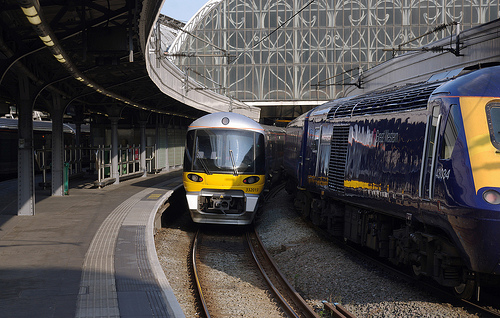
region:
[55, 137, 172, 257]
The station has no people.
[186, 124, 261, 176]
The train has one big window.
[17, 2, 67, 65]
The lights at the station are turned on.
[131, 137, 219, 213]
The train is next to the platform.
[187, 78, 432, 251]
The train is next to the big, blue train.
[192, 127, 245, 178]
The train has two windshield wipers.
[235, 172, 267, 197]
The train has numbers on it.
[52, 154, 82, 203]
The trash can is next to the pole.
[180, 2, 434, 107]
The walkway is above the trains.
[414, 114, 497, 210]
The train is blue and yellow.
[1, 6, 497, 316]
two trains on railroad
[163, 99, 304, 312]
train is on railroad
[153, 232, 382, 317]
railroad is covered with gravel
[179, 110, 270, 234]
front train is yellow and gray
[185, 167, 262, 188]
the headlights of train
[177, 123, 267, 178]
windshield in front a train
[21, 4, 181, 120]
lights on the ceiling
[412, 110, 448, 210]
the handles are color silver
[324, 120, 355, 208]
vents on side a train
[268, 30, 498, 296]
train is color blue and yellow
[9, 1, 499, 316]
two trains are at a station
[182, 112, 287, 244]
the train is at a platform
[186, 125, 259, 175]
the engine's front window has windshield wipers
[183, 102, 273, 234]
the engine is yellow and white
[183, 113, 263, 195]
the headlights on the train are off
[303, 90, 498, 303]
the engine is blue and yellow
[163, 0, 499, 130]
the station building has decorative piping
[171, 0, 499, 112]
the building's shape is curved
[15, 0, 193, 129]
the station's platform lighting is on the ceiling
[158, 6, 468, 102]
pantographs are over the tracks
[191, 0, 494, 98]
ornately constructed train station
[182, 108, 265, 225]
yellow and silver train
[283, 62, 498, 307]
blue and yellow train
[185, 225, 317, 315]
curving iron train tracks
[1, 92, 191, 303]
empty curved train platform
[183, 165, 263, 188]
headlights on the front of a train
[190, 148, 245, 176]
windshield wipers on front of train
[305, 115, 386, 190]
reflection of yellow and silver train on side of train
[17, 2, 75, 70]
lights under train platform cover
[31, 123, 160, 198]
stairs leading up to train platform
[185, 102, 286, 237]
A yellow and grey train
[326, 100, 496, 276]
A yellow and blue train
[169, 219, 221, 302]
A metalic train truck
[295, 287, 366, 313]
A metalic train truck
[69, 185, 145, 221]
A grey walk way beside the train truck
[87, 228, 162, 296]
A grey walk way beside the train truck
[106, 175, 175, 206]
A grey walk way beside the train truck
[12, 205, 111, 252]
A grey walk way beside the train truck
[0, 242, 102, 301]
A grey walk way beside the train truck